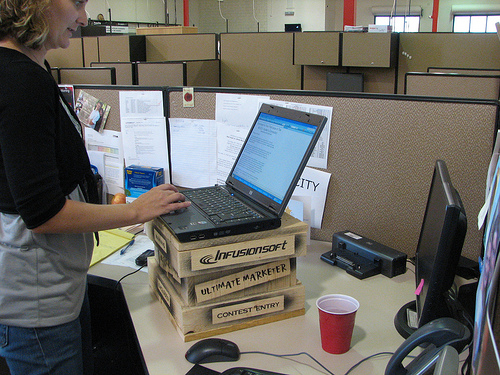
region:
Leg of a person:
[4, 303, 76, 371]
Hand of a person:
[30, 172, 191, 233]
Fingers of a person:
[144, 181, 189, 222]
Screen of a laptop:
[221, 99, 341, 211]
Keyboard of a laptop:
[148, 181, 279, 243]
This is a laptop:
[138, 81, 333, 243]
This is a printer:
[321, 221, 412, 289]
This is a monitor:
[397, 113, 489, 321]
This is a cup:
[310, 279, 364, 369]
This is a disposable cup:
[312, 285, 364, 357]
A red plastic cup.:
[312, 295, 359, 357]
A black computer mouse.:
[183, 341, 239, 361]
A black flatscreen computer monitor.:
[397, 159, 467, 347]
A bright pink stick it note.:
[412, 279, 425, 294]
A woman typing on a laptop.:
[2, 2, 331, 373]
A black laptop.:
[154, 104, 328, 244]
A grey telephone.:
[382, 315, 469, 373]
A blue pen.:
[117, 237, 137, 256]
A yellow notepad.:
[87, 229, 137, 272]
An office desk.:
[86, 186, 498, 373]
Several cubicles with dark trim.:
[31, 23, 498, 265]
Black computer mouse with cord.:
[186, 339, 461, 373]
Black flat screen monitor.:
[397, 152, 473, 339]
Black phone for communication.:
[380, 315, 474, 372]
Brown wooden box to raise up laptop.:
[143, 205, 319, 342]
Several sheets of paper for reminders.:
[76, 92, 343, 226]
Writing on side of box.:
[145, 214, 313, 342]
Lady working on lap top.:
[5, 1, 322, 371]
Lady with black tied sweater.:
[6, 3, 175, 361]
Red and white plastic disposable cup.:
[311, 294, 363, 353]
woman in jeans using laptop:
[0, 1, 195, 373]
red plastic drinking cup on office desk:
[308, 288, 365, 355]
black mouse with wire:
[180, 328, 497, 373]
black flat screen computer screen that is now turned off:
[384, 154, 478, 350]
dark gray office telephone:
[357, 311, 480, 373]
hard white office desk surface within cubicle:
[3, 199, 498, 373]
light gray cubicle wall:
[1, 82, 498, 373]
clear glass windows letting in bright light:
[363, 6, 498, 48]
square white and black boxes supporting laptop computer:
[133, 188, 318, 339]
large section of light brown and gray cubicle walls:
[1, 26, 498, 168]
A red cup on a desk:
[307, 288, 367, 360]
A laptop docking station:
[314, 212, 414, 293]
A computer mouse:
[175, 328, 245, 371]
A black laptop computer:
[139, 95, 333, 248]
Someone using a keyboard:
[115, 170, 288, 230]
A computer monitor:
[394, 152, 474, 335]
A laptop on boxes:
[145, 87, 328, 340]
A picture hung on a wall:
[67, 86, 120, 136]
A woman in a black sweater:
[2, 1, 112, 236]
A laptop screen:
[227, 100, 335, 221]